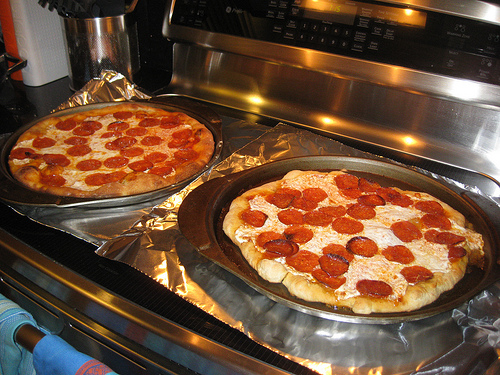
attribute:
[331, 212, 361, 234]
pepperoni — red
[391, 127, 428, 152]
light — reflecting 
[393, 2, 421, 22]
light — reflecting 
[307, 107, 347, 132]
light — reflecting 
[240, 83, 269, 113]
light — reflecting 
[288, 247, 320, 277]
pepperoni — red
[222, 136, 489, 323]
pizza — round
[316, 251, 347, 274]
pepperoni — red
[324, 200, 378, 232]
pepperoni — red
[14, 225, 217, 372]
oven — stainless steel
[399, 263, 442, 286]
pepperoni — red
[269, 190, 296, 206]
pepperoni — red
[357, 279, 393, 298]
pepperoni — red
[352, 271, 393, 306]
pepperoni — red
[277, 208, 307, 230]
pepperoni —  Red 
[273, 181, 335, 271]
pepperoni — red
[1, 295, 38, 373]
towel — light blue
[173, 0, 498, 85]
panel — black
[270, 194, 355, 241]
pepperoni piece — red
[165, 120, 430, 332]
pizza — red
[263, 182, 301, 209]
pepperoni — red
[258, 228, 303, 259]
pepporoni — red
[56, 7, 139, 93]
container — metal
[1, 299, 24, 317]
stripe — white